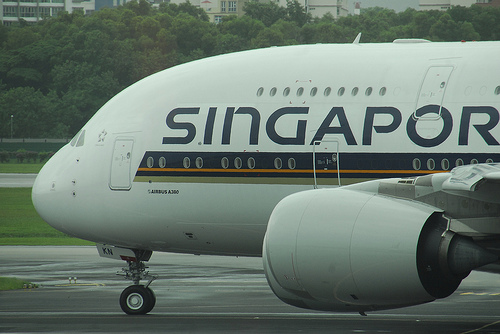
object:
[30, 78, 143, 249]
nose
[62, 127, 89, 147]
front windows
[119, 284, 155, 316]
wheel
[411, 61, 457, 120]
door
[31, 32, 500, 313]
side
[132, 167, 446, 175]
lines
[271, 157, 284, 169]
windows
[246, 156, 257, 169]
window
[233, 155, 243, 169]
window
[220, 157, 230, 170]
window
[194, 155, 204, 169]
window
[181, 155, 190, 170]
window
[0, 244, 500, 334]
runway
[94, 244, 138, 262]
model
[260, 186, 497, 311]
engine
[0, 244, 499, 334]
ground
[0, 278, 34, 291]
grass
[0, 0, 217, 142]
trees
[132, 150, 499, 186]
stripe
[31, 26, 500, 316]
plane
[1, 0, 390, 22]
buildings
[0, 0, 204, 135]
leaves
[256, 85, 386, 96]
windows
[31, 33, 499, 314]
airplane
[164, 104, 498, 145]
singapor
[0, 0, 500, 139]
forest